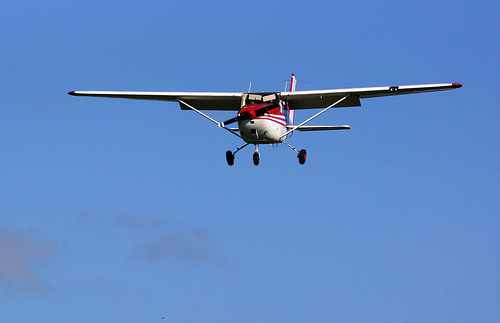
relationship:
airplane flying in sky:
[53, 56, 476, 172] [3, 3, 499, 319]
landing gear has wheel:
[225, 139, 309, 173] [224, 149, 237, 167]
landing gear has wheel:
[225, 139, 309, 173] [253, 151, 263, 168]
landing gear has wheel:
[225, 139, 309, 173] [299, 147, 307, 165]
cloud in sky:
[4, 203, 215, 322] [3, 3, 499, 319]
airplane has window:
[53, 56, 476, 172] [246, 94, 262, 103]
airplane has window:
[53, 56, 476, 172] [264, 92, 280, 103]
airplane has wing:
[53, 56, 476, 172] [284, 81, 464, 109]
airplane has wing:
[53, 56, 476, 172] [69, 88, 240, 127]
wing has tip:
[284, 81, 464, 109] [451, 79, 463, 92]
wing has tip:
[69, 88, 240, 127] [68, 87, 78, 99]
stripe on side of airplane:
[250, 111, 291, 125] [53, 56, 476, 172]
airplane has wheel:
[53, 56, 476, 172] [224, 149, 237, 167]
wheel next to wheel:
[253, 151, 263, 168] [299, 147, 307, 165]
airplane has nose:
[53, 56, 476, 172] [235, 103, 274, 139]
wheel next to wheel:
[253, 151, 263, 168] [224, 149, 237, 167]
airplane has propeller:
[53, 56, 476, 172] [216, 103, 281, 133]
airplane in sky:
[53, 56, 476, 172] [3, 3, 499, 319]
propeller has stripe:
[216, 103, 281, 133] [217, 122, 223, 129]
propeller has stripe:
[216, 103, 281, 133] [222, 119, 227, 126]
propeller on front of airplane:
[216, 103, 281, 133] [2, 3, 499, 323]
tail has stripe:
[285, 73, 298, 129] [286, 76, 296, 118]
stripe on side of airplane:
[250, 104, 299, 132] [53, 56, 476, 172]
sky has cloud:
[3, 3, 499, 319] [4, 203, 215, 322]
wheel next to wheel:
[224, 149, 237, 167] [253, 151, 263, 168]